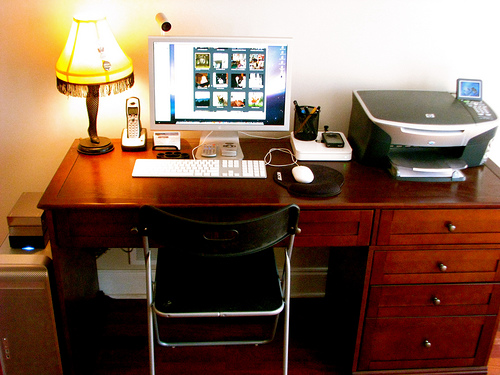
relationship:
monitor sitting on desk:
[148, 34, 291, 139] [33, 136, 496, 374]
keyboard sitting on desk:
[129, 152, 269, 182] [33, 136, 496, 374]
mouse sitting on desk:
[291, 164, 320, 187] [33, 136, 496, 374]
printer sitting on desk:
[351, 88, 500, 185] [33, 136, 496, 374]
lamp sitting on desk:
[56, 11, 133, 162] [33, 136, 496, 374]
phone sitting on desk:
[121, 94, 149, 155] [33, 136, 496, 374]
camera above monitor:
[152, 11, 177, 34] [148, 34, 291, 139]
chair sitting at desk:
[138, 202, 302, 372] [33, 136, 496, 374]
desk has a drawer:
[33, 136, 496, 374] [364, 314, 480, 375]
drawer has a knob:
[364, 314, 480, 375] [417, 334, 432, 348]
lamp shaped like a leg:
[56, 11, 133, 162] [84, 84, 102, 143]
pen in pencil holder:
[291, 100, 315, 132] [295, 105, 320, 144]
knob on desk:
[417, 334, 432, 348] [33, 136, 496, 374]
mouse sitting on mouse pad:
[291, 164, 320, 187] [273, 162, 346, 199]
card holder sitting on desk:
[146, 139, 182, 152] [33, 136, 496, 374]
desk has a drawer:
[33, 136, 496, 374] [388, 209, 499, 240]